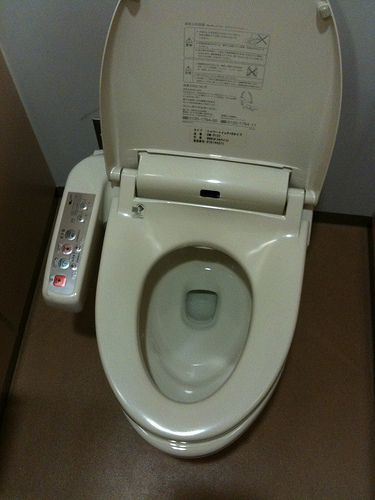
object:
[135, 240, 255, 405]
water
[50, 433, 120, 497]
ground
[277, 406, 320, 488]
brown ground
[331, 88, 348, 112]
ground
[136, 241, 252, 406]
bowl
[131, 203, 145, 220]
sticker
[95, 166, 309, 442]
seat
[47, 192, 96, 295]
control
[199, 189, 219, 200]
hole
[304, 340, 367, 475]
floor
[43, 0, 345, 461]
toilet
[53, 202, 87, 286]
button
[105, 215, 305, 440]
toilet bowl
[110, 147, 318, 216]
hinge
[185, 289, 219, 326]
drain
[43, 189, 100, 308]
silver support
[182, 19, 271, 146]
instructions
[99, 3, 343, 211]
lid